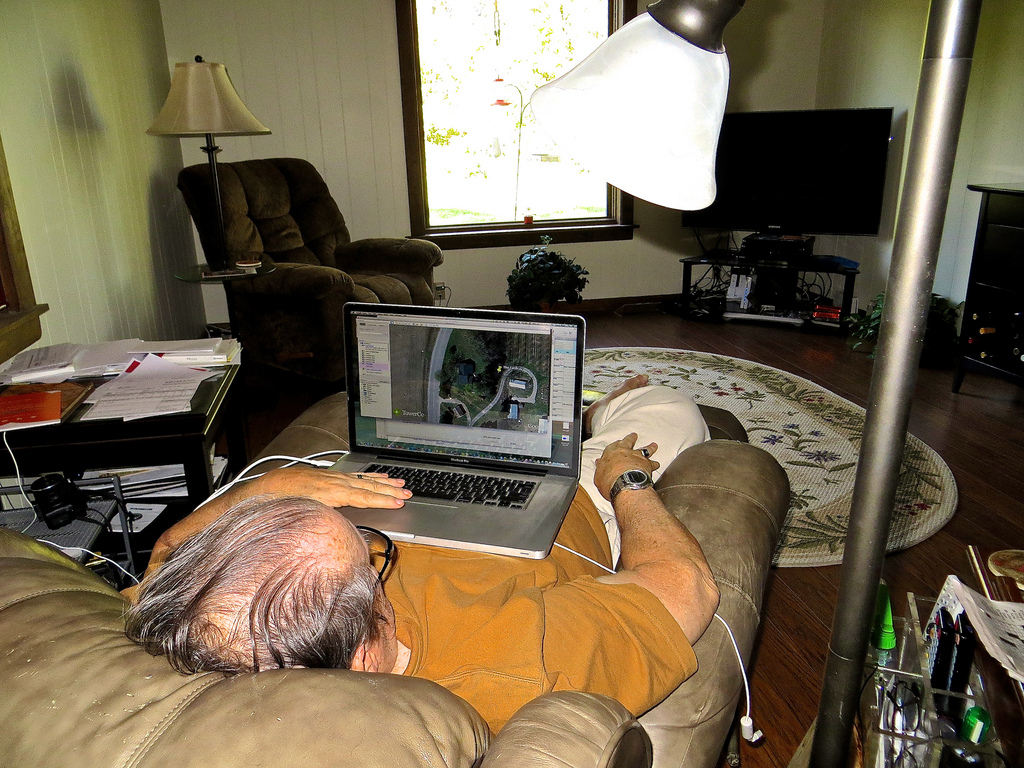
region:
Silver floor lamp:
[516, 3, 979, 766]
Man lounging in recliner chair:
[132, 371, 722, 735]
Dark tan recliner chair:
[2, 377, 793, 767]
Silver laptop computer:
[321, 298, 587, 564]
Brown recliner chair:
[184, 154, 442, 377]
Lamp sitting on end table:
[150, 55, 274, 268]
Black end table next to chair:
[4, 337, 245, 519]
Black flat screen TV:
[688, 107, 888, 238]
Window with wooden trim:
[405, 1, 637, 246]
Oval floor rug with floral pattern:
[567, 343, 957, 566]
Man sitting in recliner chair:
[132, 371, 722, 733]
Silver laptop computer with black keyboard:
[337, 300, 588, 567]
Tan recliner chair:
[2, 382, 796, 766]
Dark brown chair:
[178, 160, 445, 380]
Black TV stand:
[680, 240, 862, 342]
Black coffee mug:
[23, 469, 90, 533]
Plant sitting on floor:
[504, 239, 588, 322]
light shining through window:
[400, 3, 634, 239]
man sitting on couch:
[126, 433, 734, 738]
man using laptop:
[133, 300, 719, 715]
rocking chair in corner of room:
[179, 155, 443, 339]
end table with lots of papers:
[0, 334, 244, 459]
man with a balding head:
[128, 493, 397, 684]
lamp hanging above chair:
[524, 0, 777, 228]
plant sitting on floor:
[506, 247, 589, 314]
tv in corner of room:
[721, 107, 896, 336]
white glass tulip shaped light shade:
[516, 10, 739, 204]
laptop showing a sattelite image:
[341, 307, 585, 554]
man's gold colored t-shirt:
[382, 493, 690, 713]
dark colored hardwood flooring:
[592, 310, 1022, 757]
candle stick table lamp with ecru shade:
[146, 41, 263, 273]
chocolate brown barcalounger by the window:
[170, 164, 449, 376]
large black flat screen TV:
[708, 107, 896, 243]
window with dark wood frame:
[392, 1, 637, 245]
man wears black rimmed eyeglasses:
[358, 508, 401, 584]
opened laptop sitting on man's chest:
[333, 296, 589, 565]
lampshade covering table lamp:
[144, 57, 269, 143]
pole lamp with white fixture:
[519, 0, 987, 764]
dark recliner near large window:
[176, 153, 449, 387]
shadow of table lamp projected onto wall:
[45, 51, 143, 337]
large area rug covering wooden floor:
[555, 341, 968, 573]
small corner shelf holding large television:
[654, 251, 869, 334]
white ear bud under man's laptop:
[555, 540, 772, 755]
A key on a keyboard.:
[458, 484, 474, 497]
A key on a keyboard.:
[495, 491, 511, 504]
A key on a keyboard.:
[499, 479, 515, 492]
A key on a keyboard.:
[443, 465, 456, 482]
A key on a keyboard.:
[423, 475, 437, 486]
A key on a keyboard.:
[405, 472, 416, 483]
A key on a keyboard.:
[388, 466, 402, 479]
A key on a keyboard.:
[462, 490, 476, 501]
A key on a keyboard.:
[429, 472, 440, 483]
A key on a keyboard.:
[506, 487, 526, 498]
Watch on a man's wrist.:
[600, 455, 658, 507]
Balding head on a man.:
[132, 453, 377, 676]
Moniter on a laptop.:
[334, 293, 587, 483]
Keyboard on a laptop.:
[347, 443, 550, 523]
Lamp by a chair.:
[132, 42, 282, 292]